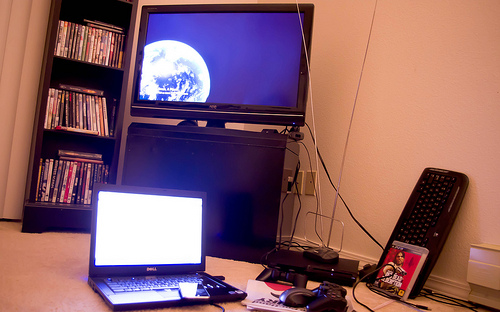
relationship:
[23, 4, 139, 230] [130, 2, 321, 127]
movie shelf by television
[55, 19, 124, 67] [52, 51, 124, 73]
movies on shelf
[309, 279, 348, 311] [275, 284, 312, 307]
controller by mouse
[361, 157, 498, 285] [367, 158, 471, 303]
case leaning on keyboard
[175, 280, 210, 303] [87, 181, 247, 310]
cell phone on laptop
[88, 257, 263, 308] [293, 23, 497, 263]
keyboard propped on wall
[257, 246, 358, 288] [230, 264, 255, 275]
playstation sitting on floor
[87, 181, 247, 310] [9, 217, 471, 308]
laptop on floor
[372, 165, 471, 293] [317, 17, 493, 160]
black keyboard leaning on wall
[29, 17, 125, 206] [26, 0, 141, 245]
dvd on shelf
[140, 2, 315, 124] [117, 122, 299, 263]
flat-screen television on stand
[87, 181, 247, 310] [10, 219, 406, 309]
laptop sitting on carpet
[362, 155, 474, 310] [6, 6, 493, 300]
keyboard against wall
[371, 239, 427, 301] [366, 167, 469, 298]
video game leaning on keyboard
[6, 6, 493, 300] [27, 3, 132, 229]
wall has bookcase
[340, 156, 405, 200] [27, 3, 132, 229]
wall has bookcase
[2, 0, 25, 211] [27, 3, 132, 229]
wall has bookcase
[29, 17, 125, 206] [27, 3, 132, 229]
dvd in bookcase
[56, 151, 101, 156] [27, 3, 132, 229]
dvd in bookcase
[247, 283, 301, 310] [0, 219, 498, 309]
remote on floor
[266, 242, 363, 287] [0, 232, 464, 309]
system on floor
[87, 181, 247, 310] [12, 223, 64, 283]
laptop on floor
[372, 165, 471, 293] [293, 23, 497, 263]
black keyboard leaning against wall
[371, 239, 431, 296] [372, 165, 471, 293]
red cd leaning against black keyboard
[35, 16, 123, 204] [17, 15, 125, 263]
cds on shelves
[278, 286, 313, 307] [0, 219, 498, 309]
mouse on floor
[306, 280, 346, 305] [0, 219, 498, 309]
remote on floor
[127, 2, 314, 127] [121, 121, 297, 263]
tv on platform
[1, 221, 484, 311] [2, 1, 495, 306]
carpet in living room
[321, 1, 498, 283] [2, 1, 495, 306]
walls in living room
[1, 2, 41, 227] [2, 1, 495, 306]
walls in living room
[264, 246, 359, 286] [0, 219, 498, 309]
cd player on floor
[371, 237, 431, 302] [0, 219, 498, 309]
movie on floor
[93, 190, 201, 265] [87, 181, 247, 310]
screen on laptop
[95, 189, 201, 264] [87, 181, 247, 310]
lit screen on laptop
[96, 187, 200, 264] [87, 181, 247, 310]
white screen on laptop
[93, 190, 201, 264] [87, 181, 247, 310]
bright screen on laptop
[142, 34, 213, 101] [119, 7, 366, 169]
moon on tv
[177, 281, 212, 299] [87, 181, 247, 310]
cell phone laying on laptop